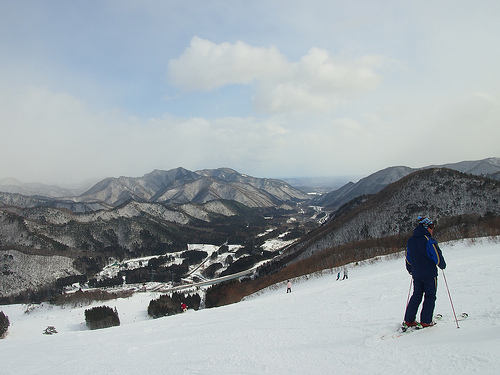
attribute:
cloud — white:
[167, 34, 382, 91]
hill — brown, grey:
[263, 165, 498, 272]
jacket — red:
[178, 302, 188, 307]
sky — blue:
[0, 5, 494, 173]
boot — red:
[400, 320, 418, 329]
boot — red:
[417, 320, 435, 327]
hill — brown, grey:
[83, 170, 243, 234]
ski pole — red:
[441, 268, 459, 329]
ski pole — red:
[400, 276, 412, 327]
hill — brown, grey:
[308, 157, 499, 212]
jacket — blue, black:
[403, 223, 446, 280]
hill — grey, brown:
[337, 175, 475, 238]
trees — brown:
[192, 231, 269, 283]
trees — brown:
[39, 287, 133, 307]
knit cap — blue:
[417, 217, 432, 230]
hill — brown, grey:
[201, 195, 253, 220]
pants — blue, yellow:
[402, 266, 442, 326]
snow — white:
[74, 310, 136, 343]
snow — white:
[362, 317, 477, 355]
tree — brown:
[121, 259, 189, 281]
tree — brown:
[174, 245, 204, 265]